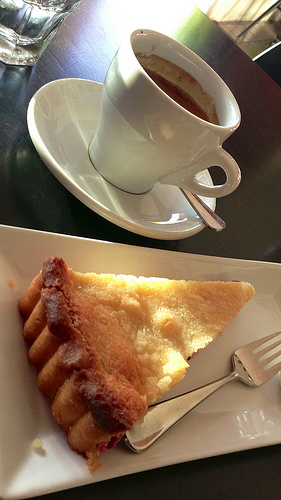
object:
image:
[0, 0, 281, 500]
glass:
[0, 0, 80, 67]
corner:
[0, 0, 92, 114]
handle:
[159, 146, 241, 197]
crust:
[18, 255, 135, 474]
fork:
[123, 331, 280, 454]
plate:
[27, 76, 217, 240]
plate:
[0, 223, 281, 499]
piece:
[167, 278, 256, 350]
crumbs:
[8, 278, 16, 291]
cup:
[88, 27, 242, 198]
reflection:
[6, 124, 77, 232]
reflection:
[55, 110, 81, 150]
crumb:
[30, 438, 47, 457]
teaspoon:
[178, 188, 226, 232]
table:
[0, 0, 281, 261]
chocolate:
[136, 53, 219, 125]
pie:
[18, 256, 255, 472]